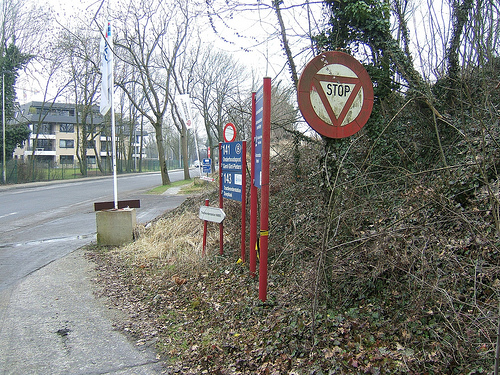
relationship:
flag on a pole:
[100, 24, 110, 109] [107, 62, 118, 205]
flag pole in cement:
[105, 19, 118, 214] [93, 209, 143, 245]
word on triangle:
[326, 82, 351, 97] [316, 70, 358, 125]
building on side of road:
[8, 102, 148, 167] [5, 193, 67, 207]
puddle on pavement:
[3, 229, 94, 246] [2, 182, 156, 267]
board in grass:
[217, 142, 248, 206] [175, 268, 260, 330]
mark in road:
[49, 319, 72, 340] [0, 188, 107, 308]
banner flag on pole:
[175, 92, 197, 130] [191, 130, 203, 176]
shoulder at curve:
[6, 245, 189, 374] [1, 187, 91, 372]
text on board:
[224, 145, 240, 202] [195, 151, 290, 215]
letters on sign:
[203, 209, 220, 219] [190, 201, 238, 236]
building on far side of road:
[15, 99, 151, 174] [4, 155, 208, 289]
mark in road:
[52, 322, 76, 360] [0, 184, 198, 239]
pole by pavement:
[257, 76, 275, 306] [0, 167, 197, 374]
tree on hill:
[325, 2, 449, 124] [138, 57, 498, 373]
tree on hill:
[445, 0, 477, 91] [138, 57, 498, 373]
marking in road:
[0, 210, 17, 219] [0, 177, 97, 373]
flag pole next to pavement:
[92, 7, 133, 214] [0, 167, 197, 374]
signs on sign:
[293, 49, 375, 141] [296, 51, 375, 136]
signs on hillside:
[198, 49, 384, 294] [145, 31, 491, 372]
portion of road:
[9, 192, 74, 227] [5, 172, 206, 322]